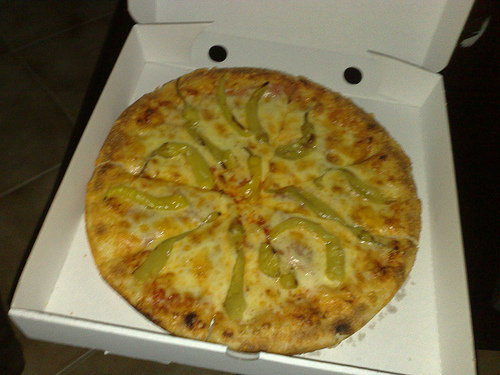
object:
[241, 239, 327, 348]
part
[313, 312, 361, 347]
edge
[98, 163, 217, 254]
part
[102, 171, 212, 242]
part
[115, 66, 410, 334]
pizza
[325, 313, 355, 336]
edge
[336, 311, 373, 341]
edge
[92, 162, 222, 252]
part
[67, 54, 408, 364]
food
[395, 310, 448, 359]
box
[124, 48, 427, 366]
pie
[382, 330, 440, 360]
box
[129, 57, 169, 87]
box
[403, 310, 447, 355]
box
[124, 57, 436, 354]
pizza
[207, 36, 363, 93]
holes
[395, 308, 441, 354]
box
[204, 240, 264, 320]
peppers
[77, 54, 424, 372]
pizza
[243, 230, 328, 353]
slice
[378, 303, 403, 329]
grease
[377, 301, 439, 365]
box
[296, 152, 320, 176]
cheese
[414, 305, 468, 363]
box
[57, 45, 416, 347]
pizza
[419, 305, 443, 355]
box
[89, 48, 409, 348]
pizza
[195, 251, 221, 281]
cheese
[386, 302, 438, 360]
box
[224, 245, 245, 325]
peppers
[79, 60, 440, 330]
pizza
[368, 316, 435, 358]
box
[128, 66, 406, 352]
pizza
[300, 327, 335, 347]
crust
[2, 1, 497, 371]
floor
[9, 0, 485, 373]
box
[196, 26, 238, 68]
hole